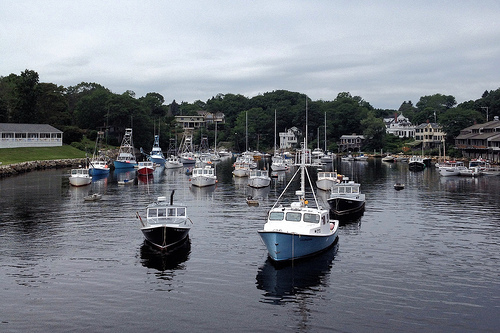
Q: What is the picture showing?
A: It is showing a river.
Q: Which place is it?
A: It is a river.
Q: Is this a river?
A: Yes, it is a river.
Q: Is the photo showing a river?
A: Yes, it is showing a river.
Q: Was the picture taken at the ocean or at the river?
A: It was taken at the river.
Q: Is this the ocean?
A: No, it is the river.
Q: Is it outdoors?
A: Yes, it is outdoors.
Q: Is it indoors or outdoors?
A: It is outdoors.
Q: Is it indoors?
A: No, it is outdoors.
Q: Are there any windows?
A: Yes, there are windows.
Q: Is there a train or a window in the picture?
A: Yes, there are windows.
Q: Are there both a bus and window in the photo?
A: No, there are windows but no buses.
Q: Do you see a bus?
A: No, there are no buses.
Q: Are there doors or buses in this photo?
A: No, there are no buses or doors.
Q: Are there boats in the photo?
A: Yes, there is a boat.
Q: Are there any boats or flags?
A: Yes, there is a boat.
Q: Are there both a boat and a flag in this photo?
A: No, there is a boat but no flags.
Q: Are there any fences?
A: No, there are no fences.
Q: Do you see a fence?
A: No, there are no fences.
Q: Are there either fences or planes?
A: No, there are no fences or planes.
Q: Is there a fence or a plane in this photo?
A: No, there are no fences or airplanes.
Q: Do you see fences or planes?
A: No, there are no fences or planes.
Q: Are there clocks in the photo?
A: No, there are no clocks.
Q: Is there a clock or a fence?
A: No, there are no clocks or fences.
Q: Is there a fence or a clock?
A: No, there are no clocks or fences.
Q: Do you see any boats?
A: Yes, there is a boat.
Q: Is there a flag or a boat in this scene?
A: Yes, there is a boat.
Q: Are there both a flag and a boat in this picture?
A: No, there is a boat but no flags.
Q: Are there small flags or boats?
A: Yes, there is a small boat.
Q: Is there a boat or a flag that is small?
A: Yes, the boat is small.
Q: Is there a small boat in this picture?
A: Yes, there is a small boat.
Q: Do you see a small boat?
A: Yes, there is a small boat.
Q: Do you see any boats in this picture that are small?
A: Yes, there is a boat that is small.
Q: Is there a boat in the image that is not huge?
A: Yes, there is a small boat.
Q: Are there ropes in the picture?
A: No, there are no ropes.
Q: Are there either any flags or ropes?
A: No, there are no ropes or flags.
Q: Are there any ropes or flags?
A: No, there are no ropes or flags.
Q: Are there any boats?
A: Yes, there is a boat.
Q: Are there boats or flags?
A: Yes, there is a boat.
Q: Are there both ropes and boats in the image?
A: No, there is a boat but no ropes.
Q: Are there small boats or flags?
A: Yes, there is a small boat.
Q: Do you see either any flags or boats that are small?
A: Yes, the boat is small.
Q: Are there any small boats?
A: Yes, there is a small boat.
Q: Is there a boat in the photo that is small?
A: Yes, there is a boat that is small.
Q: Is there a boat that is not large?
A: Yes, there is a small boat.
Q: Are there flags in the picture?
A: No, there are no flags.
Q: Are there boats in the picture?
A: Yes, there is a boat.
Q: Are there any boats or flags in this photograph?
A: Yes, there is a boat.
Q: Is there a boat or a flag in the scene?
A: Yes, there is a boat.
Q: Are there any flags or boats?
A: Yes, there is a boat.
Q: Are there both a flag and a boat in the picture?
A: No, there is a boat but no flags.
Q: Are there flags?
A: No, there are no flags.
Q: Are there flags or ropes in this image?
A: No, there are no flags or ropes.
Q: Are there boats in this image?
A: Yes, there is a boat.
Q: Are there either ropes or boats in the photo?
A: Yes, there is a boat.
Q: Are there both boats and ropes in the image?
A: No, there is a boat but no ropes.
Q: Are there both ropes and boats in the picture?
A: No, there is a boat but no ropes.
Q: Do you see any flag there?
A: No, there are no flags.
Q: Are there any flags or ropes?
A: No, there are no flags or ropes.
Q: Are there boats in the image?
A: Yes, there is a boat.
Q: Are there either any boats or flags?
A: Yes, there is a boat.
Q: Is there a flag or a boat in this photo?
A: Yes, there is a boat.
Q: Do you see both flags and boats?
A: No, there is a boat but no flags.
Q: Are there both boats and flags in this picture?
A: No, there is a boat but no flags.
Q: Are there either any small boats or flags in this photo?
A: Yes, there is a small boat.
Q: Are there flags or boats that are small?
A: Yes, the boat is small.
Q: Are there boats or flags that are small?
A: Yes, the boat is small.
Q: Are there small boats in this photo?
A: Yes, there is a small boat.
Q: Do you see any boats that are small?
A: Yes, there is a small boat.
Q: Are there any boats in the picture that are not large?
A: Yes, there is a small boat.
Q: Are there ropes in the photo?
A: No, there are no ropes.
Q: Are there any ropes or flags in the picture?
A: No, there are no ropes or flags.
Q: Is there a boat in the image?
A: Yes, there is a boat.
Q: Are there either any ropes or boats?
A: Yes, there is a boat.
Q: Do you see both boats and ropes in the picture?
A: No, there is a boat but no ropes.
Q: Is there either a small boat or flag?
A: Yes, there is a small boat.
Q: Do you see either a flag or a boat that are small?
A: Yes, the boat is small.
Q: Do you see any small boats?
A: Yes, there is a small boat.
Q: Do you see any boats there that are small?
A: Yes, there is a boat that is small.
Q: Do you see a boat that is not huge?
A: Yes, there is a small boat.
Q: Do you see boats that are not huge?
A: Yes, there is a small boat.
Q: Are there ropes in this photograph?
A: No, there are no ropes.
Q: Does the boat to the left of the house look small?
A: Yes, the boat is small.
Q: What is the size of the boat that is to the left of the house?
A: The boat is small.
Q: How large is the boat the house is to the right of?
A: The boat is small.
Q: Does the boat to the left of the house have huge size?
A: No, the boat is small.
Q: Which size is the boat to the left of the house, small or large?
A: The boat is small.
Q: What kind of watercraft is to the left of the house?
A: The watercraft is a boat.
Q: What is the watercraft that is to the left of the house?
A: The watercraft is a boat.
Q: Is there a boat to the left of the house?
A: Yes, there is a boat to the left of the house.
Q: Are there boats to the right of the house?
A: No, the boat is to the left of the house.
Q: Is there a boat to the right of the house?
A: No, the boat is to the left of the house.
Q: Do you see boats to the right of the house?
A: No, the boat is to the left of the house.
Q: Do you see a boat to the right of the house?
A: No, the boat is to the left of the house.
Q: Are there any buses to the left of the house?
A: No, there is a boat to the left of the house.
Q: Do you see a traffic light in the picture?
A: No, there are no traffic lights.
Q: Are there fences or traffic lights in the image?
A: No, there are no traffic lights or fences.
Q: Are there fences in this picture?
A: No, there are no fences.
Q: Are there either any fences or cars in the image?
A: No, there are no fences or cars.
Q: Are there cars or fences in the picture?
A: No, there are no fences or cars.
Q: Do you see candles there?
A: No, there are no candles.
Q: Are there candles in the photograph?
A: No, there are no candles.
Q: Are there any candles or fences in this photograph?
A: No, there are no candles or fences.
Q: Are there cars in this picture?
A: No, there are no cars.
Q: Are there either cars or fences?
A: No, there are no cars or fences.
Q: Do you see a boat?
A: Yes, there is a boat.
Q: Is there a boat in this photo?
A: Yes, there is a boat.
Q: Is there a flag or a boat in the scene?
A: Yes, there is a boat.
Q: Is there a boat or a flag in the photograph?
A: Yes, there is a boat.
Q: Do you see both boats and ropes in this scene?
A: No, there is a boat but no ropes.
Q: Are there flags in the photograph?
A: No, there are no flags.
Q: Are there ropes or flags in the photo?
A: No, there are no flags or ropes.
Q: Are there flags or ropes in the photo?
A: No, there are no flags or ropes.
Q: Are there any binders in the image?
A: No, there are no binders.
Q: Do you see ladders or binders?
A: No, there are no binders or ladders.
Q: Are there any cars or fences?
A: No, there are no cars or fences.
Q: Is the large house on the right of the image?
A: Yes, the house is on the right of the image.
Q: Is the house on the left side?
A: No, the house is on the right of the image.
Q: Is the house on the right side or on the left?
A: The house is on the right of the image.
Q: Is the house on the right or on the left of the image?
A: The house is on the right of the image.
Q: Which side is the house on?
A: The house is on the right of the image.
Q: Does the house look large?
A: Yes, the house is large.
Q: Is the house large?
A: Yes, the house is large.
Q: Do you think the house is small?
A: No, the house is large.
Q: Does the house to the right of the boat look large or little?
A: The house is large.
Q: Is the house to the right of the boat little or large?
A: The house is large.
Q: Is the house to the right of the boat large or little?
A: The house is large.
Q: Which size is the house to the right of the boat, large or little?
A: The house is large.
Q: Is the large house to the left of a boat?
A: No, the house is to the right of a boat.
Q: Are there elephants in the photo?
A: No, there are no elephants.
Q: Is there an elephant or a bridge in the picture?
A: No, there are no elephants or bridges.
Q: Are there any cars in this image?
A: No, there are no cars.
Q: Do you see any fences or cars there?
A: No, there are no cars or fences.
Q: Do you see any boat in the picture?
A: Yes, there is a boat.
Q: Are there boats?
A: Yes, there is a boat.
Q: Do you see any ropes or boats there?
A: Yes, there is a boat.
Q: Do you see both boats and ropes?
A: No, there is a boat but no ropes.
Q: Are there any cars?
A: No, there are no cars.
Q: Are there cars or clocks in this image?
A: No, there are no cars or clocks.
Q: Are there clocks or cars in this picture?
A: No, there are no cars or clocks.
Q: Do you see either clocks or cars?
A: No, there are no cars or clocks.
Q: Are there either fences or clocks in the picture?
A: No, there are no fences or clocks.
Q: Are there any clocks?
A: No, there are no clocks.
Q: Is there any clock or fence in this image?
A: No, there are no clocks or fences.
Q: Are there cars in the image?
A: No, there are no cars.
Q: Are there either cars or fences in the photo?
A: No, there are no cars or fences.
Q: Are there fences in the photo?
A: No, there are no fences.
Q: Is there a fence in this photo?
A: No, there are no fences.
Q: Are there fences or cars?
A: No, there are no fences or cars.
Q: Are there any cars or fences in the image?
A: No, there are no fences or cars.